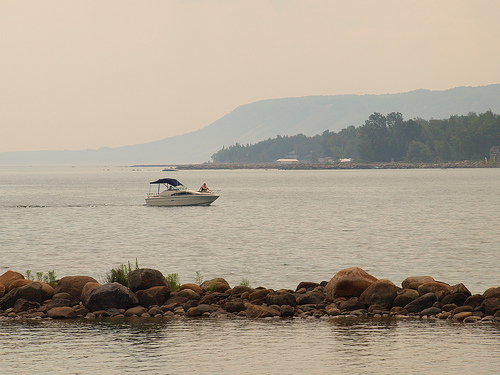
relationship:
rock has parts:
[85, 285, 134, 308] [97, 290, 130, 296]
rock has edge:
[85, 285, 134, 308] [97, 290, 130, 296]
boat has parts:
[146, 174, 220, 209] [150, 194, 159, 200]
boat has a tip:
[146, 174, 220, 209] [216, 192, 222, 199]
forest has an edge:
[208, 110, 499, 163] [216, 112, 499, 161]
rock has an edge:
[85, 285, 134, 308] [97, 290, 130, 296]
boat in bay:
[146, 174, 220, 209] [1, 162, 499, 297]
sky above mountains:
[2, 4, 499, 154] [179, 82, 499, 165]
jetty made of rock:
[1, 268, 499, 329] [85, 285, 134, 308]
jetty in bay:
[1, 268, 499, 329] [1, 162, 499, 297]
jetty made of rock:
[1, 268, 499, 329] [325, 267, 378, 300]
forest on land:
[208, 110, 499, 163] [215, 156, 499, 162]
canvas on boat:
[149, 178, 186, 188] [146, 174, 220, 209]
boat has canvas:
[146, 174, 220, 209] [149, 178, 186, 188]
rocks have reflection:
[1, 268, 499, 329] [2, 316, 496, 334]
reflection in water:
[2, 316, 496, 334] [2, 318, 499, 374]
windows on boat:
[173, 192, 198, 196] [146, 174, 220, 209]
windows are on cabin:
[173, 192, 198, 196] [174, 191, 215, 201]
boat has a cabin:
[146, 174, 220, 209] [174, 191, 215, 201]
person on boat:
[199, 182, 208, 194] [146, 174, 220, 209]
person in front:
[199, 182, 208, 194] [201, 191, 221, 202]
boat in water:
[146, 174, 220, 209] [1, 162, 499, 297]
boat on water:
[146, 174, 220, 209] [1, 162, 499, 297]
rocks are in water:
[1, 268, 499, 329] [1, 162, 499, 297]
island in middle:
[161, 170, 177, 173] [167, 169, 177, 176]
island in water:
[161, 170, 177, 173] [1, 162, 499, 297]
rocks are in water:
[1, 268, 499, 329] [1, 166, 500, 374]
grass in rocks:
[25, 258, 250, 293] [1, 268, 499, 329]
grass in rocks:
[240, 277, 249, 288] [1, 268, 499, 329]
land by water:
[125, 160, 499, 170] [1, 166, 500, 374]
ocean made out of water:
[1, 162, 499, 297] [1, 166, 500, 374]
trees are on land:
[208, 110, 499, 163] [215, 156, 499, 162]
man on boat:
[199, 182, 208, 194] [146, 174, 220, 209]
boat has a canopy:
[146, 174, 220, 209] [149, 178, 186, 188]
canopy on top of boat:
[149, 178, 186, 188] [146, 174, 220, 209]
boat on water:
[146, 174, 220, 209] [1, 166, 500, 374]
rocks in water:
[1, 268, 499, 329] [1, 166, 500, 374]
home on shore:
[481, 146, 499, 167] [438, 161, 499, 171]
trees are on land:
[208, 110, 499, 163] [125, 160, 499, 170]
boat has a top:
[146, 174, 220, 209] [149, 178, 186, 188]